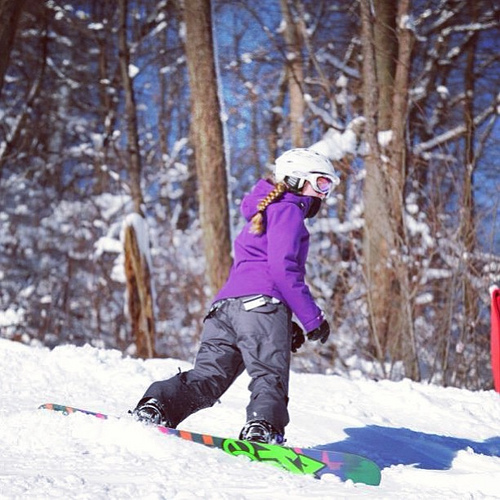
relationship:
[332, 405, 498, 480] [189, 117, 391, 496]
shadow of snowboarder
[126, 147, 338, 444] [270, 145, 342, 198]
person wearing helmet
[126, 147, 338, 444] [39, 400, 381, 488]
person standing on snowboard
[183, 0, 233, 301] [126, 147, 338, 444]
trunk behind person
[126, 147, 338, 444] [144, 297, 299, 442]
person wearing pants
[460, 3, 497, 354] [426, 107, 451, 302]
tree next to tree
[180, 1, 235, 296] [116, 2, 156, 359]
tree next to tree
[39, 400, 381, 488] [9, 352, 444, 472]
snowboard in snow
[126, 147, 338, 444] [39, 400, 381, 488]
person on snowboard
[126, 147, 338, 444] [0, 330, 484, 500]
person on snow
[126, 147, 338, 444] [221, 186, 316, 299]
person with jacket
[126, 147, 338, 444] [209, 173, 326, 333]
person wearing purple sweater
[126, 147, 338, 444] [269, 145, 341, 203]
person wearing helmet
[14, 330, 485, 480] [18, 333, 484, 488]
snow covered ground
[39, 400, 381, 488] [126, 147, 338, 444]
snowboard used by person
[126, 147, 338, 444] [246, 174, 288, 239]
person has pony tail